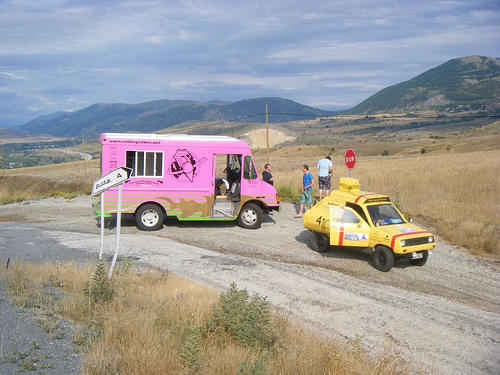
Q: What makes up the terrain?
A: Mountains.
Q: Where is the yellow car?
A: Next to the stop sign.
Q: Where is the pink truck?
A: Left from the yellow car.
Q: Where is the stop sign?
A: Behind the yellow car.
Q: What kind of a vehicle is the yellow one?
A: A delivery car.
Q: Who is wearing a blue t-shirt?
A: The young man standing in the middle.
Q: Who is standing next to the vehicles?
A: Three men.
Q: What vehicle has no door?
A: The pink one.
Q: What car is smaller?
A: The yellow one.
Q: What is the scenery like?
A: Fields and mountains.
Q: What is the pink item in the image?
A: Delivery truck.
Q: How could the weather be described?
A: Partly cloudy.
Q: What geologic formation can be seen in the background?
A: Mountains.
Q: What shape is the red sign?
A: An octagon.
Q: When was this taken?
A: During the day.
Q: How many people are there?
A: Three.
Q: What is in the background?
A: Mountains.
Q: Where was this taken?
A: On the side of the road.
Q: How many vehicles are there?
A: Two.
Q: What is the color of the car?
A: Yellow.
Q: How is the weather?
A: Cloudy.